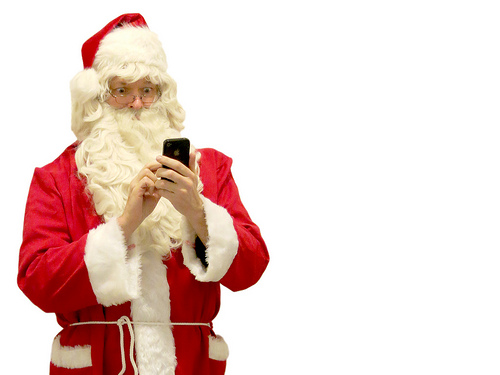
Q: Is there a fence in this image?
A: No, there are no fences.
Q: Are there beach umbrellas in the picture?
A: No, there are no beach umbrellas.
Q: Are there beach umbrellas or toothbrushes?
A: No, there are no beach umbrellas or toothbrushes.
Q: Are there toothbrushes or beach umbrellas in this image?
A: No, there are no beach umbrellas or toothbrushes.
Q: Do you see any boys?
A: No, there are no boys.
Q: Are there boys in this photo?
A: No, there are no boys.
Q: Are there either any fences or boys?
A: No, there are no boys or fences.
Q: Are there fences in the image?
A: No, there are no fences.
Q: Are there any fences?
A: No, there are no fences.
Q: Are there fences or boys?
A: No, there are no fences or boys.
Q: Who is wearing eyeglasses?
A: The man is wearing eyeglasses.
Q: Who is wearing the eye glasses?
A: The man is wearing eyeglasses.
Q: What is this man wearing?
A: The man is wearing eyeglasses.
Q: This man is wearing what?
A: The man is wearing eyeglasses.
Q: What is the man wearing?
A: The man is wearing eyeglasses.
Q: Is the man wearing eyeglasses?
A: Yes, the man is wearing eyeglasses.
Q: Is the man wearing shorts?
A: No, the man is wearing eyeglasses.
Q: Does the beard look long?
A: Yes, the beard is long.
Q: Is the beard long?
A: Yes, the beard is long.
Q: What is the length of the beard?
A: The beard is long.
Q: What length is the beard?
A: The beard is long.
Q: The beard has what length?
A: The beard is long.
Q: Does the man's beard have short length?
A: No, the beard is long.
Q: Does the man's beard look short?
A: No, the beard is long.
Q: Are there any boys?
A: No, there are no boys.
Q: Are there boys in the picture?
A: No, there are no boys.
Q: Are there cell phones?
A: Yes, there is a cell phone.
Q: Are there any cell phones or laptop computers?
A: Yes, there is a cell phone.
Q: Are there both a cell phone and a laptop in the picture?
A: No, there is a cell phone but no laptops.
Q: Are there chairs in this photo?
A: No, there are no chairs.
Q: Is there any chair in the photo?
A: No, there are no chairs.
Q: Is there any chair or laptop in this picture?
A: No, there are no chairs or laptops.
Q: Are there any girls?
A: No, there are no girls.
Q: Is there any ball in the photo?
A: Yes, there is a ball.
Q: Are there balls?
A: Yes, there is a ball.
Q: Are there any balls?
A: Yes, there is a ball.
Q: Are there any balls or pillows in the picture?
A: Yes, there is a ball.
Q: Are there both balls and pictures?
A: No, there is a ball but no pictures.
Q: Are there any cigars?
A: No, there are no cigars.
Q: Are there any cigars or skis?
A: No, there are no cigars or skis.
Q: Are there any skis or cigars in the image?
A: No, there are no cigars or skis.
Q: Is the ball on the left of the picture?
A: Yes, the ball is on the left of the image.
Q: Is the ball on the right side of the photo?
A: No, the ball is on the left of the image.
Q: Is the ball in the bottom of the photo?
A: No, the ball is in the top of the image.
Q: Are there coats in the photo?
A: Yes, there is a coat.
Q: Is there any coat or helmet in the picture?
A: Yes, there is a coat.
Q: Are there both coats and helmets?
A: No, there is a coat but no helmets.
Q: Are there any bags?
A: No, there are no bags.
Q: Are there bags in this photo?
A: No, there are no bags.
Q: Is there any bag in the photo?
A: No, there are no bags.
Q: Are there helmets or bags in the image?
A: No, there are no bags or helmets.